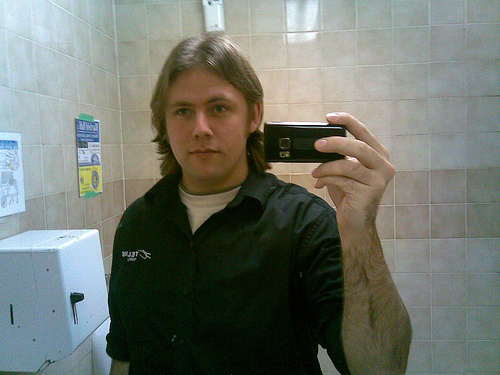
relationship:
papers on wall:
[0, 115, 105, 219] [1, 2, 123, 266]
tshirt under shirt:
[111, 178, 341, 373] [105, 179, 361, 374]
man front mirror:
[116, 23, 416, 374] [0, 1, 499, 373]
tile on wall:
[429, 170, 468, 205] [113, 1, 499, 371]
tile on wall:
[464, 168, 499, 203] [113, 1, 499, 371]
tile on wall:
[468, 130, 498, 167] [113, 1, 499, 371]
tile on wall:
[393, 135, 429, 170] [113, 1, 499, 371]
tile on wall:
[429, 240, 466, 276] [113, 1, 499, 371]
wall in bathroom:
[113, 1, 499, 371] [0, 2, 498, 372]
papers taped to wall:
[0, 115, 105, 219] [1, 0, 123, 373]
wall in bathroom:
[1, 0, 123, 373] [0, 2, 498, 372]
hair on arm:
[351, 233, 396, 327] [324, 195, 413, 370]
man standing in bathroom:
[116, 23, 416, 374] [0, 2, 498, 372]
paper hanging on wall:
[75, 115, 105, 197] [1, 0, 123, 373]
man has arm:
[116, 23, 416, 374] [294, 123, 474, 373]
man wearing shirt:
[116, 23, 416, 374] [105, 179, 361, 374]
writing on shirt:
[119, 247, 153, 262] [105, 179, 361, 374]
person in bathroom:
[95, 35, 412, 372] [0, 2, 498, 372]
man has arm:
[92, 32, 431, 373] [322, 202, 427, 374]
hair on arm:
[350, 255, 385, 344] [322, 202, 427, 374]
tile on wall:
[430, 167, 466, 202] [0, 2, 498, 373]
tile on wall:
[430, 24, 465, 60] [0, 2, 498, 373]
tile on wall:
[428, 60, 465, 97] [0, 2, 498, 373]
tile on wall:
[430, 95, 465, 130] [0, 2, 498, 373]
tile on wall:
[430, 130, 467, 167] [0, 2, 498, 373]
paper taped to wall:
[75, 115, 104, 197] [1, 0, 123, 373]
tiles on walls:
[401, 144, 476, 236] [296, 28, 463, 123]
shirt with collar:
[105, 179, 308, 371] [227, 169, 279, 216]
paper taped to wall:
[75, 115, 105, 197] [38, 20, 109, 101]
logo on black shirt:
[113, 235, 161, 276] [116, 225, 233, 324]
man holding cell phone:
[92, 32, 431, 373] [261, 122, 348, 163]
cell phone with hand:
[261, 122, 348, 163] [309, 112, 395, 229]